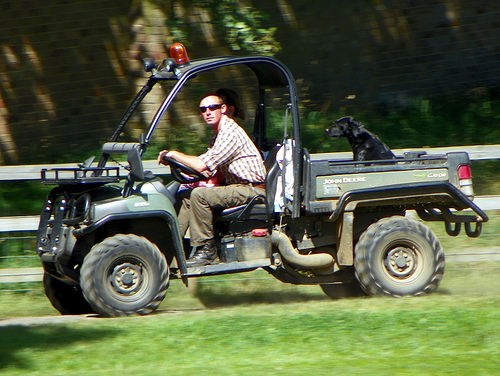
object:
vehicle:
[30, 48, 492, 319]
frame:
[96, 46, 305, 236]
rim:
[383, 246, 418, 279]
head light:
[456, 163, 473, 179]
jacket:
[263, 140, 320, 212]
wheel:
[346, 206, 451, 300]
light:
[168, 40, 189, 64]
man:
[178, 115, 270, 185]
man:
[157, 93, 266, 265]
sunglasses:
[198, 103, 223, 113]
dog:
[322, 112, 397, 161]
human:
[157, 92, 267, 266]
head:
[197, 95, 227, 125]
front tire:
[77, 232, 175, 319]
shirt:
[201, 115, 271, 183]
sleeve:
[194, 132, 235, 173]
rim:
[110, 258, 144, 295]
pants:
[171, 181, 271, 265]